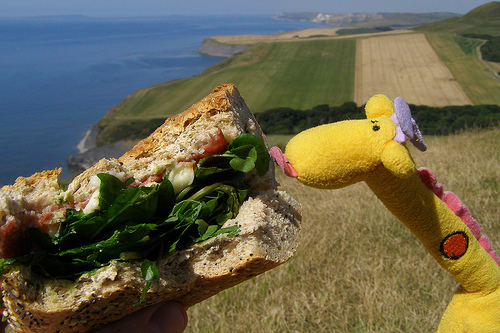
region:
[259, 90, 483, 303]
giraffe toy is yellow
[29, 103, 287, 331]
the sandwich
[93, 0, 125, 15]
this is the sky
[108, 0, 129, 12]
the sky is blue in color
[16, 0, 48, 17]
the sky has clouds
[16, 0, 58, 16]
the clouds are white in color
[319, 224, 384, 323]
this is the grass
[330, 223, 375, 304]
the grass is green in color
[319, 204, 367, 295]
the grass is short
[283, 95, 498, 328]
this is a doll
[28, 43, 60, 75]
this is the water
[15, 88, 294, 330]
this is a sandwich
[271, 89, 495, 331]
Stuffed giraffe in the forefront.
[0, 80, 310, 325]
Sandwich in the forefront.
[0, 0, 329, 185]
Blue water in the background.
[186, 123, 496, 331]
Grass covering the ground.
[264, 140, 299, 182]
tongue on the giraffe.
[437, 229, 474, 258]
Red circle on the giraffe.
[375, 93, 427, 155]
Purple hat on the giraffe.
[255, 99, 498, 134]
Trees in the background.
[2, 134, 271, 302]
Lettuce on the sandwich.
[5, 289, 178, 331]
Seeds on the crust.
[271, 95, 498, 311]
stuffed toy pretending to eat sandwich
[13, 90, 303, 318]
sandwich next to stuffed toy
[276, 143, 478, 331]
light grass on the field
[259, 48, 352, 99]
greener grass in distance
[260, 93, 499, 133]
row of green shrubs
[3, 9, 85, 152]
body of water down below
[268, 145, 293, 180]
pink tongue on stuffed toy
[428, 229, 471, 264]
orange spot on toy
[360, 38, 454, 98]
light colored area next to green terrain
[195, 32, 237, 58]
ledge next to water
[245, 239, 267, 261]
BREAD MADE OUT OF WHEAT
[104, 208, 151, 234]
GREEN LEAF IN BETWEEN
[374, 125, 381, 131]
BLACK EYES ON THE FACE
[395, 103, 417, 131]
SMALL HAT ON THE HEAD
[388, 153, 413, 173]
BIG EARS HANGING OFF THE SIDE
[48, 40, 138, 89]
BLUE WATER IN THE LAKE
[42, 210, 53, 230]
MEAT IN BETWEEN THE BREAD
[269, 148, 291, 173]
TONGUE ON THE SANDWICH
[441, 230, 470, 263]
RED CIRCLE ON THE NECK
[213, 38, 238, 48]
BIG ROCK ON THE BEACH